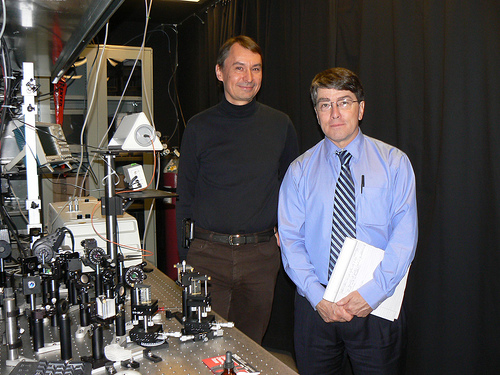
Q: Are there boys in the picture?
A: No, there are no boys.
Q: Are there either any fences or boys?
A: No, there are no boys or fences.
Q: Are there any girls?
A: No, there are no girls.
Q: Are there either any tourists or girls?
A: No, there are no girls or tourists.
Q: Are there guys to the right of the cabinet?
A: Yes, there are guys to the right of the cabinet.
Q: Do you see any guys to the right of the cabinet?
A: Yes, there are guys to the right of the cabinet.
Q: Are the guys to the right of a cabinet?
A: Yes, the guys are to the right of a cabinet.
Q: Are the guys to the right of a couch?
A: No, the guys are to the right of a cabinet.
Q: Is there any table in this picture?
A: Yes, there is a table.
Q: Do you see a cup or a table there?
A: Yes, there is a table.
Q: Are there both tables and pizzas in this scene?
A: No, there is a table but no pizzas.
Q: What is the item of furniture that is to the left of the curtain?
A: The piece of furniture is a table.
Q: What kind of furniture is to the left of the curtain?
A: The piece of furniture is a table.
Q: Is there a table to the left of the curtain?
A: Yes, there is a table to the left of the curtain.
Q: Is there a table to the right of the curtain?
A: No, the table is to the left of the curtain.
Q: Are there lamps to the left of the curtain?
A: No, there is a table to the left of the curtain.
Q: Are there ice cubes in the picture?
A: No, there are no ice cubes.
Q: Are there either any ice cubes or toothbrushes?
A: No, there are no ice cubes or toothbrushes.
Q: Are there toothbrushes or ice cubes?
A: No, there are no ice cubes or toothbrushes.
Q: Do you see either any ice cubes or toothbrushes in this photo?
A: No, there are no ice cubes or toothbrushes.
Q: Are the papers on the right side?
A: Yes, the papers are on the right of the image.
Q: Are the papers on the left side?
A: No, the papers are on the right of the image.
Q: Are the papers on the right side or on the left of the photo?
A: The papers are on the right of the image.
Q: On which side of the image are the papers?
A: The papers are on the right of the image.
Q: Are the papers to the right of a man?
A: Yes, the papers are to the right of a man.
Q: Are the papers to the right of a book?
A: No, the papers are to the right of a man.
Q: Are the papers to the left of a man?
A: No, the papers are to the right of a man.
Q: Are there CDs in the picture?
A: No, there are no cds.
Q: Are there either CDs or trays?
A: No, there are no CDs or trays.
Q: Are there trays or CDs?
A: No, there are no CDs or trays.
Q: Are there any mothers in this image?
A: No, there are no mothers.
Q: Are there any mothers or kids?
A: No, there are no mothers or kids.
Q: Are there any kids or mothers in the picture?
A: No, there are no mothers or kids.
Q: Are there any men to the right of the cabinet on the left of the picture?
A: Yes, there is a man to the right of the cabinet.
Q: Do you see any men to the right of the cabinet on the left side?
A: Yes, there is a man to the right of the cabinet.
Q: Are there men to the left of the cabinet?
A: No, the man is to the right of the cabinet.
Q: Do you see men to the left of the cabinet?
A: No, the man is to the right of the cabinet.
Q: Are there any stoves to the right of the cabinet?
A: No, there is a man to the right of the cabinet.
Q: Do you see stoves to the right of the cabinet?
A: No, there is a man to the right of the cabinet.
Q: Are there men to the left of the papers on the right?
A: Yes, there is a man to the left of the papers.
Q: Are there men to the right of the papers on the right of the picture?
A: No, the man is to the left of the papers.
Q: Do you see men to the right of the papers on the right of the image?
A: No, the man is to the left of the papers.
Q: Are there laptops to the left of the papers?
A: No, there is a man to the left of the papers.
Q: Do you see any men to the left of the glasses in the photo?
A: Yes, there is a man to the left of the glasses.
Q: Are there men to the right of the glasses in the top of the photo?
A: No, the man is to the left of the glasses.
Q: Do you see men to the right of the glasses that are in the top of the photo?
A: No, the man is to the left of the glasses.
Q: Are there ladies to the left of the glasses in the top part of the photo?
A: No, there is a man to the left of the glasses.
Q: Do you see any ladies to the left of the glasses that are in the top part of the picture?
A: No, there is a man to the left of the glasses.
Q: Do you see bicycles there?
A: No, there are no bicycles.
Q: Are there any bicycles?
A: No, there are no bicycles.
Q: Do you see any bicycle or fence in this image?
A: No, there are no bicycles or fences.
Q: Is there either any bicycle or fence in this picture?
A: No, there are no bicycles or fences.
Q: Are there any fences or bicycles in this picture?
A: No, there are no bicycles or fences.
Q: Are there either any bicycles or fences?
A: No, there are no bicycles or fences.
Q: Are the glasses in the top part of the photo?
A: Yes, the glasses are in the top of the image.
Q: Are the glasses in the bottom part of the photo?
A: No, the glasses are in the top of the image.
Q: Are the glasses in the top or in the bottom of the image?
A: The glasses are in the top of the image.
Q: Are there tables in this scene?
A: Yes, there is a table.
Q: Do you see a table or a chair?
A: Yes, there is a table.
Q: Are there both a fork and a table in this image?
A: No, there is a table but no forks.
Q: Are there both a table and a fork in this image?
A: No, there is a table but no forks.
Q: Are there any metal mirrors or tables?
A: Yes, there is a metal table.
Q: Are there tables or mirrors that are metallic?
A: Yes, the table is metallic.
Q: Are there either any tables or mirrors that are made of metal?
A: Yes, the table is made of metal.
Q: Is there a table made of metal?
A: Yes, there is a table that is made of metal.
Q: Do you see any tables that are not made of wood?
A: Yes, there is a table that is made of metal.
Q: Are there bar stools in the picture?
A: No, there are no bar stools.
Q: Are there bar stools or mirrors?
A: No, there are no bar stools or mirrors.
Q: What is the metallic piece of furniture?
A: The piece of furniture is a table.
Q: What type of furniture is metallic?
A: The furniture is a table.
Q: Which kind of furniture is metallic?
A: The furniture is a table.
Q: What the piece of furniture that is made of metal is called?
A: The piece of furniture is a table.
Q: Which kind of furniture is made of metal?
A: The furniture is a table.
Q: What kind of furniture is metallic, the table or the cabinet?
A: The table is metallic.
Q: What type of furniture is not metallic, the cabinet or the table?
A: The cabinet is not metallic.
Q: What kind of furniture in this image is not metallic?
A: The furniture is a cabinet.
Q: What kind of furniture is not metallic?
A: The furniture is a cabinet.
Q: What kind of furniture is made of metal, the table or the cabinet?
A: The table is made of metal.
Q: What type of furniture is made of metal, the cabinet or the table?
A: The table is made of metal.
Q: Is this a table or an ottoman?
A: This is a table.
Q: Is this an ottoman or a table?
A: This is a table.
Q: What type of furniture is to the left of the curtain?
A: The piece of furniture is a table.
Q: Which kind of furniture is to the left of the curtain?
A: The piece of furniture is a table.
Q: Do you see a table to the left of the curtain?
A: Yes, there is a table to the left of the curtain.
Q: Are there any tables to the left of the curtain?
A: Yes, there is a table to the left of the curtain.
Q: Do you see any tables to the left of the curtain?
A: Yes, there is a table to the left of the curtain.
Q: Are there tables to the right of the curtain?
A: No, the table is to the left of the curtain.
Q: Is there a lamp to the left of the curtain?
A: No, there is a table to the left of the curtain.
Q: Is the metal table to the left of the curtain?
A: Yes, the table is to the left of the curtain.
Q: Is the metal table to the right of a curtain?
A: No, the table is to the left of a curtain.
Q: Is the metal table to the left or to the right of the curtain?
A: The table is to the left of the curtain.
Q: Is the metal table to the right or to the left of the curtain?
A: The table is to the left of the curtain.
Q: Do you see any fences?
A: No, there are no fences.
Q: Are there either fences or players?
A: No, there are no fences or players.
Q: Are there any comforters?
A: No, there are no comforters.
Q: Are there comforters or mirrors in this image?
A: No, there are no comforters or mirrors.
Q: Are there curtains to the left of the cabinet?
A: No, the curtain is to the right of the cabinet.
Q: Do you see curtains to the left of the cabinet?
A: No, the curtain is to the right of the cabinet.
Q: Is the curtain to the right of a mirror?
A: No, the curtain is to the right of the cabinet.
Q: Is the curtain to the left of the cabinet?
A: No, the curtain is to the right of the cabinet.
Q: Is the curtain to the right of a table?
A: Yes, the curtain is to the right of a table.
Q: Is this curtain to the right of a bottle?
A: No, the curtain is to the right of a table.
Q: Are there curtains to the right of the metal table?
A: Yes, there is a curtain to the right of the table.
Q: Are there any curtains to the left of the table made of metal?
A: No, the curtain is to the right of the table.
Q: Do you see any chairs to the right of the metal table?
A: No, there is a curtain to the right of the table.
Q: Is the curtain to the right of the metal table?
A: Yes, the curtain is to the right of the table.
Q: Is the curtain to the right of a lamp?
A: No, the curtain is to the right of the table.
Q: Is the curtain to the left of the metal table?
A: No, the curtain is to the right of the table.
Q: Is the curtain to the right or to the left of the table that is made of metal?
A: The curtain is to the right of the table.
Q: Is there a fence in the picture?
A: No, there are no fences.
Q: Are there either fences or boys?
A: No, there are no fences or boys.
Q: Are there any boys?
A: No, there are no boys.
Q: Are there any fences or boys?
A: No, there are no boys or fences.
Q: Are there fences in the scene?
A: No, there are no fences.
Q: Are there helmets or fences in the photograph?
A: No, there are no fences or helmets.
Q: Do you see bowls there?
A: No, there are no bowls.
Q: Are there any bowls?
A: No, there are no bowls.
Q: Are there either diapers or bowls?
A: No, there are no bowls or diapers.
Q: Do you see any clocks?
A: No, there are no clocks.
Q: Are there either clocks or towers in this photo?
A: No, there are no clocks or towers.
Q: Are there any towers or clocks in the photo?
A: No, there are no clocks or towers.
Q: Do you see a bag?
A: No, there are no bags.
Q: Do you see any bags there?
A: No, there are no bags.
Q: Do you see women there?
A: No, there are no women.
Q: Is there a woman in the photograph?
A: No, there are no women.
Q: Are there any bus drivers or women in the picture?
A: No, there are no women or bus drivers.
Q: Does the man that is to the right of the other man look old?
A: Yes, the man is old.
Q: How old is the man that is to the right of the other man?
A: The man is old.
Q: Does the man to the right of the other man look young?
A: No, the man is old.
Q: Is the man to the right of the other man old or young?
A: The man is old.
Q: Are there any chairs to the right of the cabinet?
A: No, there is a man to the right of the cabinet.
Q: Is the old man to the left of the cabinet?
A: No, the man is to the right of the cabinet.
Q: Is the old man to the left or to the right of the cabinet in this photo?
A: The man is to the right of the cabinet.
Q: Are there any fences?
A: No, there are no fences.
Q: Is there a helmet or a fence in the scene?
A: No, there are no fences or helmets.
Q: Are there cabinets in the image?
A: Yes, there is a cabinet.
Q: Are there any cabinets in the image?
A: Yes, there is a cabinet.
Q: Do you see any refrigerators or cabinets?
A: Yes, there is a cabinet.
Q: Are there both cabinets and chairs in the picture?
A: No, there is a cabinet but no chairs.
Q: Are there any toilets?
A: No, there are no toilets.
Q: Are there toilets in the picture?
A: No, there are no toilets.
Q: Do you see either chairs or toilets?
A: No, there are no toilets or chairs.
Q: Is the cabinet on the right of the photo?
A: No, the cabinet is on the left of the image.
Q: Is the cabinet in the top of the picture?
A: Yes, the cabinet is in the top of the image.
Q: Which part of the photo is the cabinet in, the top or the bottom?
A: The cabinet is in the top of the image.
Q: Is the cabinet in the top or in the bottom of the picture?
A: The cabinet is in the top of the image.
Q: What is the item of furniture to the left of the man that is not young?
A: The piece of furniture is a cabinet.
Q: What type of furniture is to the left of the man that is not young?
A: The piece of furniture is a cabinet.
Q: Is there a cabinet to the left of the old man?
A: Yes, there is a cabinet to the left of the man.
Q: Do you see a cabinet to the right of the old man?
A: No, the cabinet is to the left of the man.